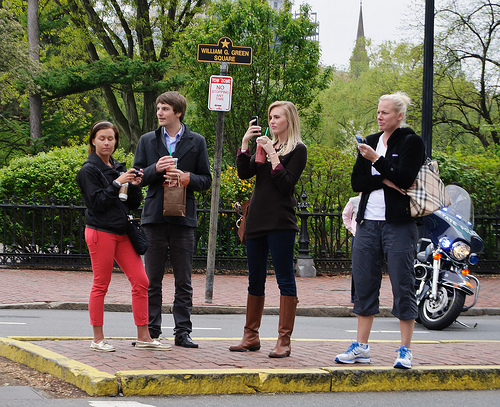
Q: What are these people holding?
A: Mobile phones.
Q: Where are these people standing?
A: In a medium in the road.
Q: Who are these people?
A: Pedestrians.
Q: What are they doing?
A: Taking photos.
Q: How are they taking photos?
A: With their cellular phones.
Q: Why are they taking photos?
A: Because their is an event happening.